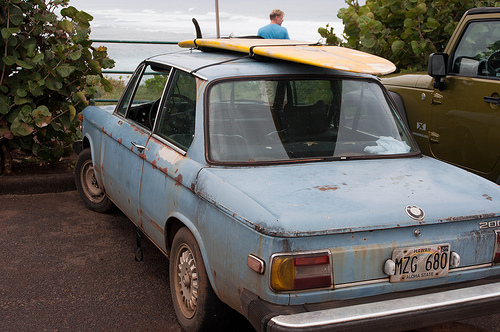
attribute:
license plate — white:
[390, 241, 452, 285]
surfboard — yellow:
[175, 30, 399, 74]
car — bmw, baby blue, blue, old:
[61, 21, 500, 331]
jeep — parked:
[409, 0, 499, 158]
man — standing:
[252, 7, 296, 44]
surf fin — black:
[190, 16, 207, 43]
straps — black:
[242, 45, 274, 65]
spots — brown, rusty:
[145, 155, 166, 168]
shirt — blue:
[253, 25, 293, 40]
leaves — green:
[64, 9, 94, 36]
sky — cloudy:
[143, 6, 213, 18]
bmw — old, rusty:
[119, 58, 413, 210]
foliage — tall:
[4, 108, 62, 174]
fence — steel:
[113, 36, 135, 83]